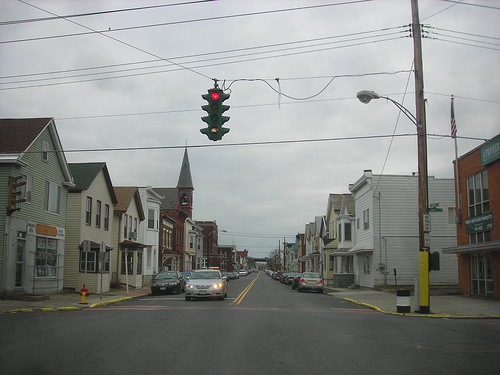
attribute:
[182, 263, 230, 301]
car — on, old, gold, white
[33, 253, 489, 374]
road — dark, grey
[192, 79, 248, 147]
light — off, hanging, red, on, black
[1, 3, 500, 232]
sky — dark, gray, grey, white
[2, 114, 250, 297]
buildings — wide, big, green, red, brown, white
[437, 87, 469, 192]
flag — red, blue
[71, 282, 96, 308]
hydrant — yellow, red